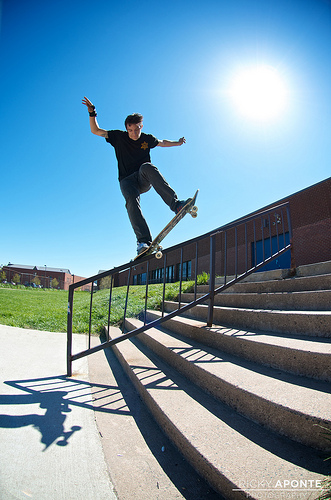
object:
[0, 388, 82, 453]
shadow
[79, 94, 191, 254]
skateboarder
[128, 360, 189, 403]
shadow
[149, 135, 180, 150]
arms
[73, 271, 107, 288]
handrail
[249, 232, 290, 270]
doors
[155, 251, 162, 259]
wheel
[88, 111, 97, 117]
watch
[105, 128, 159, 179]
shirt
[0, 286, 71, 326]
field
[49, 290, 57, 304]
grass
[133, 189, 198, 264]
skateboard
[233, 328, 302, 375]
stairs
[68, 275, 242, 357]
railing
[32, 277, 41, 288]
tree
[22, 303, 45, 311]
green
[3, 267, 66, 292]
distance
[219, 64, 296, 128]
sun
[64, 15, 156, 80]
sky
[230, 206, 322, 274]
building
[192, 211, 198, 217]
tires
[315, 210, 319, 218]
brick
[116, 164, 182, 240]
jeans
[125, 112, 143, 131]
hair